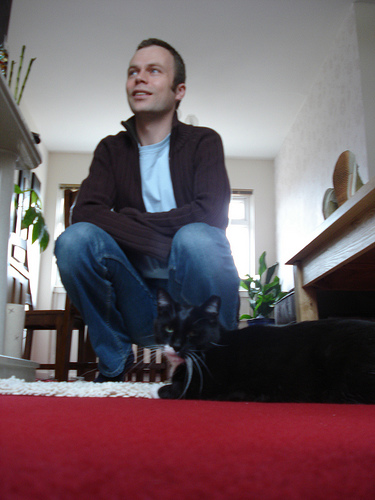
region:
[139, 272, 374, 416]
a cat lays on the floor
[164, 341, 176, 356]
the cat has a small white spot on its mouth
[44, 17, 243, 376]
a man is behind the cat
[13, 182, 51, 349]
a plant is to the left of the man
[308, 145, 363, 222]
some decorative plates are on the table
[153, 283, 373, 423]
the cats body is primarily black in color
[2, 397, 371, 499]
the floor is red in color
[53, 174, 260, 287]
a window is behind the man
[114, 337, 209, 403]
the cat has white whiskers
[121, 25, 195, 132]
the man is looking to the left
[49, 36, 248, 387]
a guy in the room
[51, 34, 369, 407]
a guy next to the cat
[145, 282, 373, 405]
a black cat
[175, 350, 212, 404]
whiskers of the cat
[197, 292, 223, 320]
an ear of the cat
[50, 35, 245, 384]
a guy squatting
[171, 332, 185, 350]
a nose of the cat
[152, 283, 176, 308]
an ear of the cat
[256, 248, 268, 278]
a leaf of the plant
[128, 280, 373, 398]
a black and white cat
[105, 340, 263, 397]
white whiskers on cat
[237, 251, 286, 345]
a plant in the corner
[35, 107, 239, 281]
a brown sweater and white shirt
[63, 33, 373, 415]
a man and a cat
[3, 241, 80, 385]
a brown wooden chair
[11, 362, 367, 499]
red carpet under cat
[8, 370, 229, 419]
a white cloth on the carpet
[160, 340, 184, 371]
a white patch on black cat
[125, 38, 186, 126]
face of a man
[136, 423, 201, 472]
part of a red carpet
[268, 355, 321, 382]
body of a big ugly cat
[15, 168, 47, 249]
green plant hanging from side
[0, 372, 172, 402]
fluffy white rug on top of red rug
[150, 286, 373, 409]
one big black cat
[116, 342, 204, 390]
whiskers of a big black ugly cat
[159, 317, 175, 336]
eye of a big ugly cat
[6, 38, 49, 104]
green bamboo sticks on a mantle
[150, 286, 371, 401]
black and white cat looking at the camera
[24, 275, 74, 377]
dark colored wood chair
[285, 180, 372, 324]
light colored wood table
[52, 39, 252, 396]
man kneeling behind a cat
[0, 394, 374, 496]
bright red carpet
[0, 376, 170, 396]
high pile white rug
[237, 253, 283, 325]
large leaved potted plant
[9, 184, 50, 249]
green leafy plant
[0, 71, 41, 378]
large white mantle